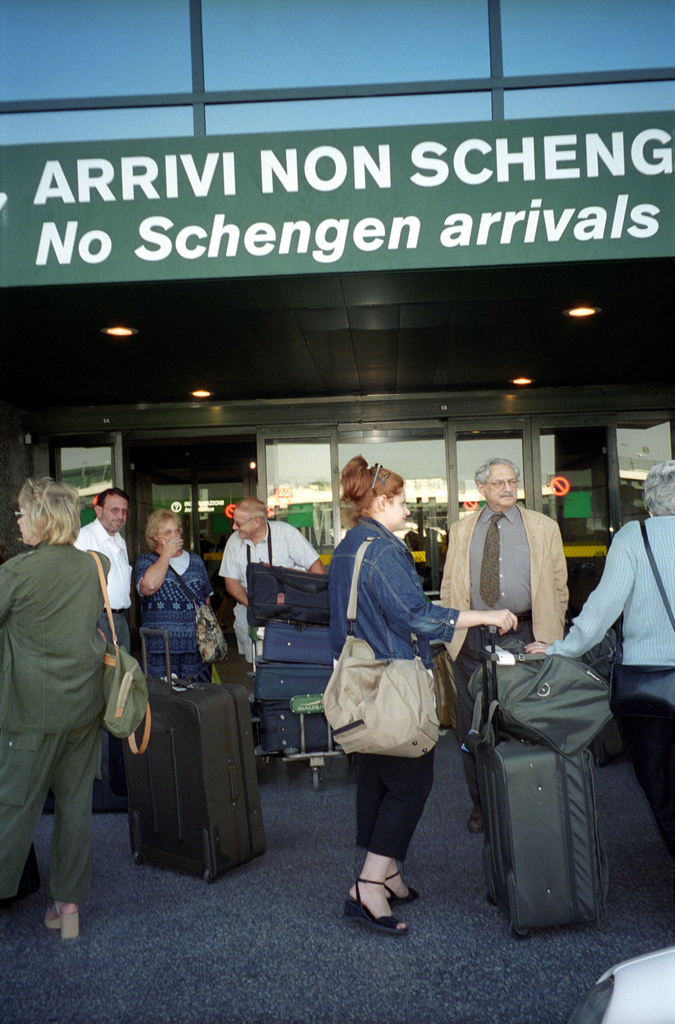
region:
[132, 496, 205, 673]
woman standing at airport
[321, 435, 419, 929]
woman standing at airport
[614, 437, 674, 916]
woman standing at airport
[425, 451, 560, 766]
man standing at airport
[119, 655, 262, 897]
large piece of luggage at airport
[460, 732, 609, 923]
large piece of luggage at airport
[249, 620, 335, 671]
large piece of luggage at airport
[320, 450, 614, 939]
woman holding onto a suitcase handle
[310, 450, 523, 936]
woman carrying tan colored bag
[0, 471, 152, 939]
woman carrying olive green purse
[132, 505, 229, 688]
woman with her hand to her face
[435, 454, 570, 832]
man wearing tan colored jacket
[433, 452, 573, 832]
man wearing short ugly tie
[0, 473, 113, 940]
woman wearing olive green top and pants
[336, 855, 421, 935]
pair of black wedge sandals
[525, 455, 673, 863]
older woman with black purse and blue sweater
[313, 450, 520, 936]
red haired woman wearing jean jacket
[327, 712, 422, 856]
woman wearing black pants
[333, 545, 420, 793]
woman holding a brown bag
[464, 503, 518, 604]
man wearing a brown tie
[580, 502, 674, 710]
woman holding a black purse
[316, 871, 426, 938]
woman wearing black shoes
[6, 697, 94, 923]
woman wearing green pants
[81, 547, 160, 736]
woman holding a green bag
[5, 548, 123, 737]
woman wearing a green jacket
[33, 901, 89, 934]
woman wearing brown shoes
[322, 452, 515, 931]
woman with long red hair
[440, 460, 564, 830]
old man in a tan jacket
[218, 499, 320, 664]
old man in a white shirt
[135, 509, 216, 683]
woman in a blue shirt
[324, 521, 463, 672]
jean jacket on the woman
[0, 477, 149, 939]
woman wearing all dark green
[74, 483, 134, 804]
man wearing a button up white shirt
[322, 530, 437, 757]
tan bag on the woman's shoulder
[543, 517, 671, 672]
gray jacket on the woman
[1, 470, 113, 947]
a person is standing up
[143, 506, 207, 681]
a person is standing up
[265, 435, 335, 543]
a window on a building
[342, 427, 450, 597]
a window on a building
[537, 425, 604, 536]
a window on a building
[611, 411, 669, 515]
a window on a building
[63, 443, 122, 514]
a window on a building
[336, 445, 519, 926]
a person is standing up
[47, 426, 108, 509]
a window on a building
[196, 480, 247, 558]
a window on a building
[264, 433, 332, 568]
a window on a building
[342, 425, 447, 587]
a window on a building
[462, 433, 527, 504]
a window on a building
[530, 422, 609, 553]
a window on a building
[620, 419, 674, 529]
a window on a building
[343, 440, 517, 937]
a person is standing up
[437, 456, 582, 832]
a person is standing up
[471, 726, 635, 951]
gray suitcase sitting in line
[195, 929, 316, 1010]
blue carpet on the ground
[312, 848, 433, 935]
black sandels on white feet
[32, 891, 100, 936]
high heeled white sandels on the ladie's foot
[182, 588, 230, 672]
flowered purse on a woman's shoulder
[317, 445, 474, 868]
woman with Red Hair waiting for their flight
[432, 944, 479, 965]
blue carpet on the ground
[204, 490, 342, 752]
man pushing his luggage to the airplane